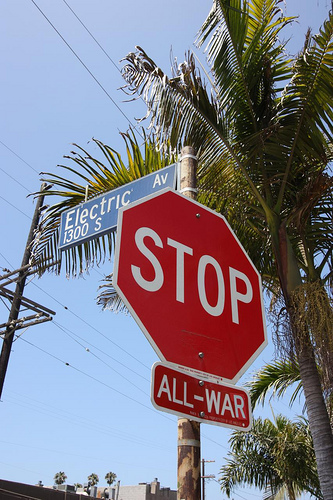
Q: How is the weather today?
A: It is sunny.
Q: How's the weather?
A: It is sunny.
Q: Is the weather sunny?
A: Yes, it is sunny.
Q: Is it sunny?
A: Yes, it is sunny.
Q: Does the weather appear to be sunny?
A: Yes, it is sunny.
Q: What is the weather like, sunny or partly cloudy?
A: It is sunny.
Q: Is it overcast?
A: No, it is sunny.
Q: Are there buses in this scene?
A: No, there are no buses.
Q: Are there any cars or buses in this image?
A: No, there are no buses or cars.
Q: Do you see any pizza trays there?
A: No, there are no pizza trays.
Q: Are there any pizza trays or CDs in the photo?
A: No, there are no pizza trays or cds.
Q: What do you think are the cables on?
A: The cables are on the post.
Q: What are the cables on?
A: The cables are on the post.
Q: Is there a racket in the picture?
A: No, there are no rackets.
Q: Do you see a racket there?
A: No, there are no rackets.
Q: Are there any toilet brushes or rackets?
A: No, there are no rackets or toilet brushes.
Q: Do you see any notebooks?
A: No, there are no notebooks.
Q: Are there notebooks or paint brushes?
A: No, there are no notebooks or paint brushes.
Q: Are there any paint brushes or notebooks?
A: No, there are no notebooks or paint brushes.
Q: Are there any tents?
A: No, there are no tents.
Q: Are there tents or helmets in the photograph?
A: No, there are no tents or helmets.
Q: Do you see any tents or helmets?
A: No, there are no tents or helmets.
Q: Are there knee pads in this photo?
A: No, there are no knee pads.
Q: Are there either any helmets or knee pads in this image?
A: No, there are no knee pads or helmets.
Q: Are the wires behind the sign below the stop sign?
A: Yes, the wires are behind the sign.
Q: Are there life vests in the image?
A: No, there are no life vests.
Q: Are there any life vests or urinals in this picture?
A: No, there are no life vests or urinals.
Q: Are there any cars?
A: No, there are no cars.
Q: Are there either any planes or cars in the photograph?
A: No, there are no cars or planes.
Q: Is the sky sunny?
A: Yes, the sky is sunny.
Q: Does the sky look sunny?
A: Yes, the sky is sunny.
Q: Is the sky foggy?
A: No, the sky is sunny.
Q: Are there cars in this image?
A: No, there are no cars.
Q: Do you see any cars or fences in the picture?
A: No, there are no cars or fences.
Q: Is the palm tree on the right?
A: Yes, the palm tree is on the right of the image.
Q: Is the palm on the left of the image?
A: No, the palm is on the right of the image.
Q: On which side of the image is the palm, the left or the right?
A: The palm is on the right of the image.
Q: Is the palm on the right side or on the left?
A: The palm is on the right of the image.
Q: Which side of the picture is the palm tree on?
A: The palm tree is on the right of the image.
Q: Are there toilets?
A: No, there are no toilets.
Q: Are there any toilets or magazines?
A: No, there are no toilets or magazines.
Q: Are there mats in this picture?
A: No, there are no mats.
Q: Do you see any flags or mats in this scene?
A: No, there are no mats or flags.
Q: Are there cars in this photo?
A: No, there are no cars.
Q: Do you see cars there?
A: No, there are no cars.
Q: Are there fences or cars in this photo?
A: No, there are no cars or fences.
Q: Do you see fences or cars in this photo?
A: No, there are no cars or fences.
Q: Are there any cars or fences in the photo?
A: No, there are no cars or fences.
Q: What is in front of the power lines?
A: The sign is in front of the power lines.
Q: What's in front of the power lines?
A: The sign is in front of the power lines.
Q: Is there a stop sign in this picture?
A: Yes, there is a stop sign.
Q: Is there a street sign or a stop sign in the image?
A: Yes, there is a stop sign.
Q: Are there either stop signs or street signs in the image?
A: Yes, there is a stop sign.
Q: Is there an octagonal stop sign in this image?
A: Yes, there is an octagonal stop sign.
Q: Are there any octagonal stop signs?
A: Yes, there is an octagonal stop sign.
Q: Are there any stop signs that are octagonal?
A: Yes, there is a stop sign that is octagonal.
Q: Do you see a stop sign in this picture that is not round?
A: Yes, there is a octagonal stop sign.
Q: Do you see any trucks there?
A: No, there are no trucks.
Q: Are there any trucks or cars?
A: No, there are no trucks or cars.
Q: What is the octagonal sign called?
A: The sign is a stop sign.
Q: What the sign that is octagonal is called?
A: The sign is a stop sign.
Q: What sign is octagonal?
A: The sign is a stop sign.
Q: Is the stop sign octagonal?
A: Yes, the stop sign is octagonal.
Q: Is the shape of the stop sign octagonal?
A: Yes, the stop sign is octagonal.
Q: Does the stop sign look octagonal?
A: Yes, the stop sign is octagonal.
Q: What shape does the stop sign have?
A: The stop sign has octagonal shape.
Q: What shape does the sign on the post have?
A: The stop sign has octagonal shape.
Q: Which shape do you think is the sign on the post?
A: The stop sign is octagonal.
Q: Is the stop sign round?
A: No, the stop sign is octagonal.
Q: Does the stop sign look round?
A: No, the stop sign is octagonal.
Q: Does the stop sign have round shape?
A: No, the stop sign is octagonal.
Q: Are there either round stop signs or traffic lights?
A: No, there is a stop sign but it is octagonal.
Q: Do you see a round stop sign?
A: No, there is a stop sign but it is octagonal.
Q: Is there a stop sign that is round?
A: No, there is a stop sign but it is octagonal.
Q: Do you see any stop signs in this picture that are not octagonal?
A: No, there is a stop sign but it is octagonal.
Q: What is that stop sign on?
A: The stop sign is on the post.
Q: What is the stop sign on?
A: The stop sign is on the post.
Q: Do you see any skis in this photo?
A: No, there are no skis.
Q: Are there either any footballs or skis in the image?
A: No, there are no skis or footballs.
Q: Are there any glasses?
A: No, there are no glasses.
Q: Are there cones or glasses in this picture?
A: No, there are no glasses or cones.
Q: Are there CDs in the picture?
A: No, there are no cds.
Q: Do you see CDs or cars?
A: No, there are no CDs or cars.